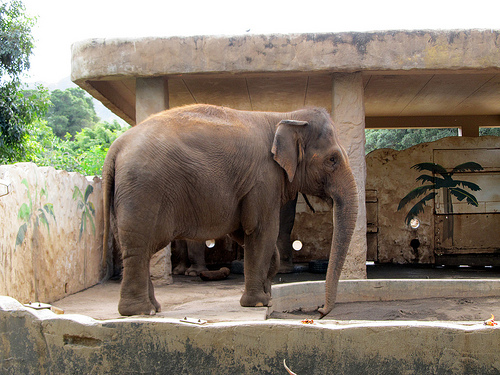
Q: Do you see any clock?
A: No, there are no clocks.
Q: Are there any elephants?
A: Yes, there is an elephant.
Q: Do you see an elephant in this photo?
A: Yes, there is an elephant.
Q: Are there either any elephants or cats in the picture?
A: Yes, there is an elephant.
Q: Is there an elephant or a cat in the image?
A: Yes, there is an elephant.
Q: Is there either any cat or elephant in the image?
A: Yes, there is an elephant.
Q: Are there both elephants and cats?
A: No, there is an elephant but no cats.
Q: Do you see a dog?
A: No, there are no dogs.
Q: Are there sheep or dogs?
A: No, there are no dogs or sheep.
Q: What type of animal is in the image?
A: The animal is an elephant.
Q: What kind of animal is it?
A: The animal is an elephant.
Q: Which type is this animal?
A: This is an elephant.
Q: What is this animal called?
A: This is an elephant.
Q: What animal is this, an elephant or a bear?
A: This is an elephant.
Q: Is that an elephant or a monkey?
A: That is an elephant.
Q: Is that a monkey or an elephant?
A: That is an elephant.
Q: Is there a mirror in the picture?
A: No, there are no mirrors.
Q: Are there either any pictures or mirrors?
A: No, there are no mirrors or pictures.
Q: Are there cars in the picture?
A: No, there are no cars.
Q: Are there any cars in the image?
A: No, there are no cars.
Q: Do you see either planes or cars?
A: No, there are no cars or planes.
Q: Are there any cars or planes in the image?
A: No, there are no cars or planes.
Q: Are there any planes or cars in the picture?
A: No, there are no cars or planes.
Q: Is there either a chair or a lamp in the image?
A: No, there are no lamps or chairs.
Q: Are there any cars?
A: No, there are no cars.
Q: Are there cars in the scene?
A: No, there are no cars.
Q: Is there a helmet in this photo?
A: No, there are no helmets.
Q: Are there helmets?
A: No, there are no helmets.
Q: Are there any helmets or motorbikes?
A: No, there are no helmets or motorbikes.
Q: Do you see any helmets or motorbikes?
A: No, there are no helmets or motorbikes.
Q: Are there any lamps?
A: No, there are no lamps.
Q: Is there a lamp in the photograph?
A: No, there are no lamps.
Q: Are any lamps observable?
A: No, there are no lamps.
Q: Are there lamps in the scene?
A: No, there are no lamps.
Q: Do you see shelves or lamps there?
A: No, there are no lamps or shelves.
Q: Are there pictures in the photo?
A: No, there are no pictures.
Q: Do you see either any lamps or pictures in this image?
A: No, there are no pictures or lamps.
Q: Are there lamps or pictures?
A: No, there are no pictures or lamps.